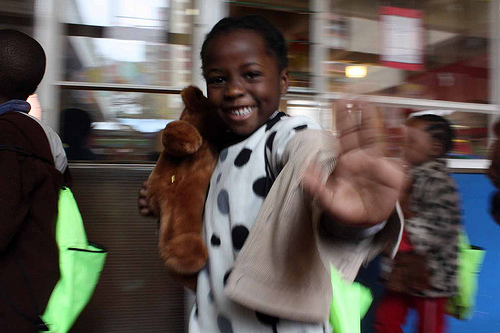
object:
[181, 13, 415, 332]
child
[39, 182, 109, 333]
backpack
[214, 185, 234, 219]
polka dots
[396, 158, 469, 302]
coat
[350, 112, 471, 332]
young child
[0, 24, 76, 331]
young child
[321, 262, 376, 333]
backpack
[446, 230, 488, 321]
backpack